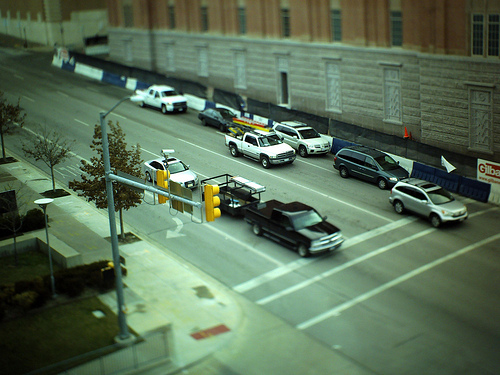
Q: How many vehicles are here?
A: 8.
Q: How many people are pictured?
A: 0.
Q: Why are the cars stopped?
A: Red light.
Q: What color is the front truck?
A: Black.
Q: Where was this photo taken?
A: On a street.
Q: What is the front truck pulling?
A: A trailer.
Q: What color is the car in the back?
A: White.